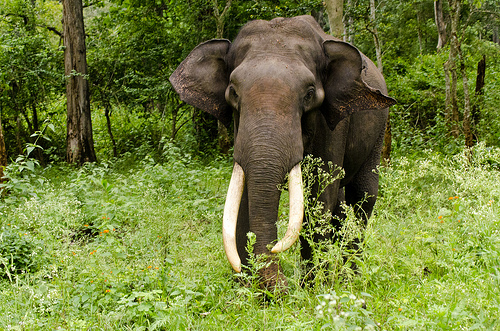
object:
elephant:
[167, 13, 398, 302]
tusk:
[270, 160, 306, 253]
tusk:
[221, 160, 247, 275]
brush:
[1, 149, 499, 329]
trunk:
[60, 1, 98, 166]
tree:
[3, 1, 135, 166]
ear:
[322, 40, 398, 134]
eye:
[302, 84, 317, 107]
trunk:
[246, 168, 287, 302]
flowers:
[5, 193, 463, 318]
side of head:
[269, 62, 326, 169]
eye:
[225, 84, 242, 108]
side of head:
[225, 60, 268, 174]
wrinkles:
[249, 123, 282, 252]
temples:
[293, 43, 324, 105]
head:
[195, 12, 354, 131]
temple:
[223, 46, 249, 117]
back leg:
[345, 126, 386, 276]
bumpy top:
[231, 14, 325, 42]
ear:
[165, 39, 232, 132]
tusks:
[222, 158, 305, 271]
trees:
[321, 1, 499, 169]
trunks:
[326, 0, 487, 161]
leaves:
[2, 115, 59, 209]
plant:
[0, 118, 59, 279]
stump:
[0, 125, 14, 202]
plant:
[62, 211, 161, 298]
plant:
[302, 153, 378, 297]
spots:
[169, 66, 219, 117]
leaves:
[1, 1, 499, 169]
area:
[0, 0, 499, 168]